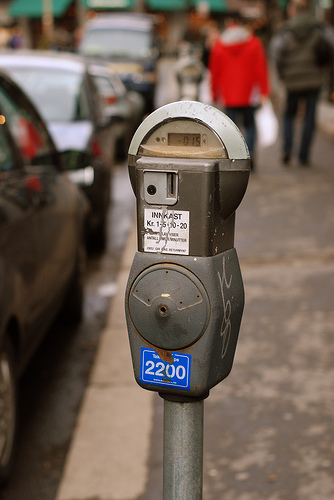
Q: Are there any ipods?
A: No, there are no ipods.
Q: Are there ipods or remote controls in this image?
A: No, there are no ipods or remote controls.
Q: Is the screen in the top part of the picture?
A: Yes, the screen is in the top of the image.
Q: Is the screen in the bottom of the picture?
A: No, the screen is in the top of the image.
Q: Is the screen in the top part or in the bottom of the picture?
A: The screen is in the top of the image.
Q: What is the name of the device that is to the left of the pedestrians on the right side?
A: The device is a screen.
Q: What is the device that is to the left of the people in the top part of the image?
A: The device is a screen.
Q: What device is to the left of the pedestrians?
A: The device is a screen.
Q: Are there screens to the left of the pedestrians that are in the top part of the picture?
A: Yes, there is a screen to the left of the pedestrians.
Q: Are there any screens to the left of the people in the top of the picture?
A: Yes, there is a screen to the left of the pedestrians.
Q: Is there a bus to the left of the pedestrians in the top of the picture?
A: No, there is a screen to the left of the pedestrians.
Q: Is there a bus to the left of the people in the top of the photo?
A: No, there is a screen to the left of the pedestrians.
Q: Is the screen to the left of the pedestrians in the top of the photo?
A: Yes, the screen is to the left of the pedestrians.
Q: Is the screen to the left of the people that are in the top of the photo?
A: Yes, the screen is to the left of the pedestrians.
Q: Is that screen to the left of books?
A: No, the screen is to the left of the pedestrians.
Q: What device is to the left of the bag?
A: The device is a screen.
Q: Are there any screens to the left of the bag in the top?
A: Yes, there is a screen to the left of the bag.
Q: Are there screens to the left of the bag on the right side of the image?
A: Yes, there is a screen to the left of the bag.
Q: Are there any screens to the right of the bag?
A: No, the screen is to the left of the bag.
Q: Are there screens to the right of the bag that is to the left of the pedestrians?
A: No, the screen is to the left of the bag.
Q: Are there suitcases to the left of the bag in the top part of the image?
A: No, there is a screen to the left of the bag.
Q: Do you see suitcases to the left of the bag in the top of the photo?
A: No, there is a screen to the left of the bag.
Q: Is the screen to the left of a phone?
A: No, the screen is to the left of the bag.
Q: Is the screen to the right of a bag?
A: No, the screen is to the left of a bag.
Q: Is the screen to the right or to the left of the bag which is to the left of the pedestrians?
A: The screen is to the left of the bag.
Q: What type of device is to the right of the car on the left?
A: The device is a screen.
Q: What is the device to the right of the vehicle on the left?
A: The device is a screen.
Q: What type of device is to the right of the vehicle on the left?
A: The device is a screen.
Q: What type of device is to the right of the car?
A: The device is a screen.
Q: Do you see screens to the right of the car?
A: Yes, there is a screen to the right of the car.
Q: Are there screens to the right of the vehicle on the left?
A: Yes, there is a screen to the right of the car.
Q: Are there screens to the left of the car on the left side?
A: No, the screen is to the right of the car.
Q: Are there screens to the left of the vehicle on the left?
A: No, the screen is to the right of the car.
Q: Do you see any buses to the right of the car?
A: No, there is a screen to the right of the car.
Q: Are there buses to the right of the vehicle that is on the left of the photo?
A: No, there is a screen to the right of the car.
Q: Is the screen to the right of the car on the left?
A: Yes, the screen is to the right of the car.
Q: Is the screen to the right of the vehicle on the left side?
A: Yes, the screen is to the right of the car.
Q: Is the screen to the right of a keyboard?
A: No, the screen is to the right of the car.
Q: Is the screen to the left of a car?
A: No, the screen is to the right of a car.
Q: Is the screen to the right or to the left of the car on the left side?
A: The screen is to the right of the car.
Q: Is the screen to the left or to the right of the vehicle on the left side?
A: The screen is to the right of the car.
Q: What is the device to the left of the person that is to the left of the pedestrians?
A: The device is a screen.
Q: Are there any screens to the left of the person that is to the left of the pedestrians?
A: Yes, there is a screen to the left of the person.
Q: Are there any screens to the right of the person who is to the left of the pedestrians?
A: No, the screen is to the left of the person.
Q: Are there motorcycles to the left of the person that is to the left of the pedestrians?
A: No, there is a screen to the left of the person.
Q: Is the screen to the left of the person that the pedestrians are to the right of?
A: Yes, the screen is to the left of the person.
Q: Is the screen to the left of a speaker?
A: No, the screen is to the left of the person.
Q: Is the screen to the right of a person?
A: No, the screen is to the left of a person.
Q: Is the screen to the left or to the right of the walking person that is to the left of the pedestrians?
A: The screen is to the left of the person.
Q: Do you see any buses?
A: No, there are no buses.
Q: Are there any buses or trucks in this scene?
A: No, there are no buses or trucks.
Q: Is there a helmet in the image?
A: No, there are no helmets.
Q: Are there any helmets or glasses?
A: No, there are no helmets or glasses.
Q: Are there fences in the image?
A: No, there are no fences.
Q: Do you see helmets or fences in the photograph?
A: No, there are no fences or helmets.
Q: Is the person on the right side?
A: Yes, the person is on the right of the image.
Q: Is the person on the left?
A: No, the person is on the right of the image.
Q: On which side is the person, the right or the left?
A: The person is on the right of the image.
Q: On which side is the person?
A: The person is on the right of the image.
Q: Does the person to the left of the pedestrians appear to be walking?
A: Yes, the person is walking.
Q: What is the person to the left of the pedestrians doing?
A: The person is walking.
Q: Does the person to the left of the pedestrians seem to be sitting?
A: No, the person is walking.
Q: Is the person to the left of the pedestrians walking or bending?
A: The person is walking.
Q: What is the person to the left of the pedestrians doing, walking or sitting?
A: The person is walking.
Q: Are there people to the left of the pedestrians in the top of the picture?
A: Yes, there is a person to the left of the pedestrians.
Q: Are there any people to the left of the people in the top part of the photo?
A: Yes, there is a person to the left of the pedestrians.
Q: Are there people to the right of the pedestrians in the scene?
A: No, the person is to the left of the pedestrians.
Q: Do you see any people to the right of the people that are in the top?
A: No, the person is to the left of the pedestrians.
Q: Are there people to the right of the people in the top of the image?
A: No, the person is to the left of the pedestrians.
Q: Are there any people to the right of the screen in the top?
A: Yes, there is a person to the right of the screen.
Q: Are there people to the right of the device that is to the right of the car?
A: Yes, there is a person to the right of the screen.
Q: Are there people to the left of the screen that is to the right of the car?
A: No, the person is to the right of the screen.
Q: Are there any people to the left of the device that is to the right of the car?
A: No, the person is to the right of the screen.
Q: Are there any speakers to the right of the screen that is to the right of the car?
A: No, there is a person to the right of the screen.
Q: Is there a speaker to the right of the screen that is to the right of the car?
A: No, there is a person to the right of the screen.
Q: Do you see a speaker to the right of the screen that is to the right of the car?
A: No, there is a person to the right of the screen.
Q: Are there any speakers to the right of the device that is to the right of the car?
A: No, there is a person to the right of the screen.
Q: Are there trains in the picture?
A: No, there are no trains.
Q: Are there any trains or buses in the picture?
A: No, there are no trains or buses.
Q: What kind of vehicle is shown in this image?
A: The vehicle is a car.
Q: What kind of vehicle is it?
A: The vehicle is a car.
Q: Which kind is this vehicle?
A: That is a car.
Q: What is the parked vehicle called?
A: The vehicle is a car.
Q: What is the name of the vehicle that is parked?
A: The vehicle is a car.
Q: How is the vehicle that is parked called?
A: The vehicle is a car.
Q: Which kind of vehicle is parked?
A: The vehicle is a car.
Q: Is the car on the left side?
A: Yes, the car is on the left of the image.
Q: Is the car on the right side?
A: No, the car is on the left of the image.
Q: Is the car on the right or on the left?
A: The car is on the left of the image.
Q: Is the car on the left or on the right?
A: The car is on the left of the image.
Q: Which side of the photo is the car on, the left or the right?
A: The car is on the left of the image.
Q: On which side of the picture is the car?
A: The car is on the left of the image.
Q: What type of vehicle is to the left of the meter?
A: The vehicle is a car.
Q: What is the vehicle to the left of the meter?
A: The vehicle is a car.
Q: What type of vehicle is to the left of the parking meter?
A: The vehicle is a car.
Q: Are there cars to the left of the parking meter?
A: Yes, there is a car to the left of the parking meter.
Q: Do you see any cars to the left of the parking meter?
A: Yes, there is a car to the left of the parking meter.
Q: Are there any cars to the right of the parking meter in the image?
A: No, the car is to the left of the parking meter.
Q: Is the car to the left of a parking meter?
A: Yes, the car is to the left of a parking meter.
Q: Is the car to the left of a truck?
A: No, the car is to the left of a parking meter.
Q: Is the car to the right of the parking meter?
A: No, the car is to the left of the parking meter.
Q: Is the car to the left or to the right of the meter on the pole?
A: The car is to the left of the parking meter.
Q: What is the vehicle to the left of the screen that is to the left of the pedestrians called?
A: The vehicle is a car.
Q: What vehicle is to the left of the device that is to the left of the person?
A: The vehicle is a car.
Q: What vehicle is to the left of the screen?
A: The vehicle is a car.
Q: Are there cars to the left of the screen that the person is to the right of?
A: Yes, there is a car to the left of the screen.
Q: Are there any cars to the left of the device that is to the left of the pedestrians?
A: Yes, there is a car to the left of the screen.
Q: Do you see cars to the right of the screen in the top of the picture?
A: No, the car is to the left of the screen.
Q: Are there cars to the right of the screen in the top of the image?
A: No, the car is to the left of the screen.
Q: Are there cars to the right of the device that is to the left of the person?
A: No, the car is to the left of the screen.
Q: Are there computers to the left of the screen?
A: No, there is a car to the left of the screen.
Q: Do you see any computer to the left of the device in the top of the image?
A: No, there is a car to the left of the screen.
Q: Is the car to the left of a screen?
A: Yes, the car is to the left of a screen.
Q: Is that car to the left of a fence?
A: No, the car is to the left of a screen.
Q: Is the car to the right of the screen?
A: No, the car is to the left of the screen.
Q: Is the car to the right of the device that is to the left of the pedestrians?
A: No, the car is to the left of the screen.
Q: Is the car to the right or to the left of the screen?
A: The car is to the left of the screen.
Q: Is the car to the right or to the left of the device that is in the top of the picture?
A: The car is to the left of the screen.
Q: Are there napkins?
A: No, there are no napkins.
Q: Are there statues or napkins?
A: No, there are no napkins or statues.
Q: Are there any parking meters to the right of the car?
A: Yes, there is a parking meter to the right of the car.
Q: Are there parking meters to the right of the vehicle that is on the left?
A: Yes, there is a parking meter to the right of the car.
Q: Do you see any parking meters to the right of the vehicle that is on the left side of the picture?
A: Yes, there is a parking meter to the right of the car.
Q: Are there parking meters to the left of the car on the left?
A: No, the parking meter is to the right of the car.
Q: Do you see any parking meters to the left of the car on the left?
A: No, the parking meter is to the right of the car.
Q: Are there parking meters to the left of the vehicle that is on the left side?
A: No, the parking meter is to the right of the car.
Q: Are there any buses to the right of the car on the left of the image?
A: No, there is a parking meter to the right of the car.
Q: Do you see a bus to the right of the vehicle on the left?
A: No, there is a parking meter to the right of the car.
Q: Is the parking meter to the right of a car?
A: Yes, the parking meter is to the right of a car.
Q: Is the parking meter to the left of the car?
A: No, the parking meter is to the right of the car.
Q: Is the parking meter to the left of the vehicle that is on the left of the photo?
A: No, the parking meter is to the right of the car.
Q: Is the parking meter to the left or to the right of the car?
A: The parking meter is to the right of the car.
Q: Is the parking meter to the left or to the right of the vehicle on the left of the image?
A: The parking meter is to the right of the car.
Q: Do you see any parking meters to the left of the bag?
A: Yes, there is a parking meter to the left of the bag.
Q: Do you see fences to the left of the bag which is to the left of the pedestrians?
A: No, there is a parking meter to the left of the bag.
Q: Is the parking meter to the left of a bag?
A: Yes, the parking meter is to the left of a bag.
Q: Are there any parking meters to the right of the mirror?
A: Yes, there is a parking meter to the right of the mirror.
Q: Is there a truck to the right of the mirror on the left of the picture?
A: No, there is a parking meter to the right of the mirror.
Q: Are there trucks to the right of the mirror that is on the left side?
A: No, there is a parking meter to the right of the mirror.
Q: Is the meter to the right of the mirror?
A: Yes, the meter is to the right of the mirror.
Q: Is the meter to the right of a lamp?
A: No, the meter is to the right of the mirror.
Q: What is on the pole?
A: The meter is on the pole.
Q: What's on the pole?
A: The meter is on the pole.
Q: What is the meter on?
A: The meter is on the pole.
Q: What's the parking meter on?
A: The meter is on the pole.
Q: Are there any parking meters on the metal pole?
A: Yes, there is a parking meter on the pole.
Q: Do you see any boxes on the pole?
A: No, there is a parking meter on the pole.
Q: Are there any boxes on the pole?
A: No, there is a parking meter on the pole.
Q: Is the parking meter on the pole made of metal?
A: Yes, the parking meter is on the pole.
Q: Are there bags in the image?
A: Yes, there is a bag.